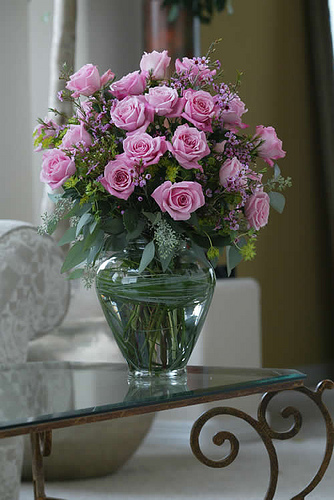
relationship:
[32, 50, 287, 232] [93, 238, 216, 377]
flowers in vase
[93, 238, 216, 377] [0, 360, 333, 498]
vase on table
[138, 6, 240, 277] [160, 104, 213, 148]
molding on wall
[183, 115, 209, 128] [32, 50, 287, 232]
buds on flowers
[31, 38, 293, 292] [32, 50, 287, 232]
buds on flowers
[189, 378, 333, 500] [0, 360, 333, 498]
designs on table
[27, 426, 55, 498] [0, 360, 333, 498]
leg on table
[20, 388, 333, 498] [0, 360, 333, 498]
carpet under table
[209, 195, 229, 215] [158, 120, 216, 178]
leaves below flower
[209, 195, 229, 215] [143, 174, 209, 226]
leaves below flower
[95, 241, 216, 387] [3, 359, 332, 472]
vase on table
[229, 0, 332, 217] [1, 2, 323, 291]
wall in background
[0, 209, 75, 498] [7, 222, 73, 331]
chair has arm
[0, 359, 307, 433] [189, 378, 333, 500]
table has designs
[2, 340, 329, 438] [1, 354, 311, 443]
table has top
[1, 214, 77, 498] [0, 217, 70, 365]
designer sofa has arm